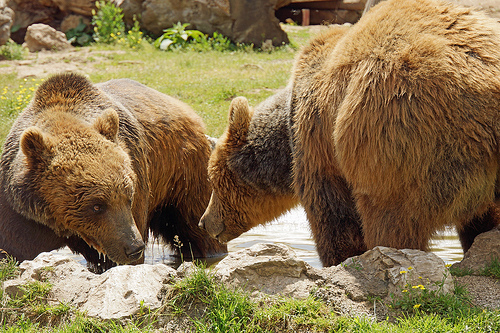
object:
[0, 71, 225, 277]
bear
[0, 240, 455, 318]
rocks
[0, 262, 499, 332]
grass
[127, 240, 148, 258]
nose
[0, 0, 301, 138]
plant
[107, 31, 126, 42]
yellow flowers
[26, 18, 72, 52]
rock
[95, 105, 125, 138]
ears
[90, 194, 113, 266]
down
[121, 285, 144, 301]
grey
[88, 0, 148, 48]
flower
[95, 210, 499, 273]
water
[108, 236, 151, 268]
bears mouth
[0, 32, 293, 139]
sunlight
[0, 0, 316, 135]
grass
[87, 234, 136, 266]
whiskers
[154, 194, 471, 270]
stream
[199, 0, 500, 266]
friends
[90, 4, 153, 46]
weeds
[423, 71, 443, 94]
brown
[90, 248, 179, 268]
drinking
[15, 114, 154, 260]
head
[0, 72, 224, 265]
fur